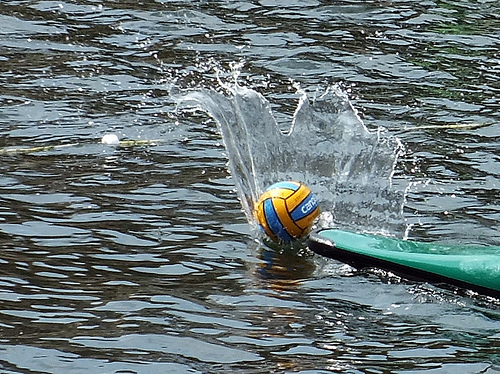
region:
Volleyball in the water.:
[249, 175, 321, 244]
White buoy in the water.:
[97, 132, 120, 147]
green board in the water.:
[305, 221, 497, 297]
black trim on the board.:
[305, 220, 341, 255]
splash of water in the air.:
[165, 57, 427, 237]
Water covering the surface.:
[1, 0, 492, 370]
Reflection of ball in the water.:
[250, 242, 315, 282]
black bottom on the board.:
[308, 223, 498, 304]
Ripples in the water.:
[2, 2, 493, 370]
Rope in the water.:
[1, 119, 497, 161]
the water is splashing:
[149, 32, 430, 250]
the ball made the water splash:
[224, 156, 339, 264]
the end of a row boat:
[291, 212, 498, 300]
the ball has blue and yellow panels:
[210, 141, 340, 256]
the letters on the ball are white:
[285, 178, 327, 228]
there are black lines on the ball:
[242, 164, 342, 250]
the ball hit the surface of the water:
[229, 139, 347, 356]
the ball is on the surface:
[227, 168, 341, 254]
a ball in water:
[228, 146, 317, 250]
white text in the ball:
[294, 177, 324, 222]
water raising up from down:
[183, 60, 447, 195]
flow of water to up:
[174, 48, 404, 178]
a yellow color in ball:
[273, 195, 294, 240]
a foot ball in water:
[228, 145, 313, 255]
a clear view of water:
[29, 18, 496, 178]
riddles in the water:
[24, 193, 374, 370]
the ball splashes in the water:
[175, 78, 476, 270]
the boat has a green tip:
[304, 216, 376, 299]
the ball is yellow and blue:
[245, 145, 434, 312]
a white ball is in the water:
[80, 110, 225, 216]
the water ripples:
[120, 223, 295, 336]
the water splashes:
[80, 13, 477, 220]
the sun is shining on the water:
[3, 23, 294, 268]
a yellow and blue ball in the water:
[258, 176, 320, 243]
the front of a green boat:
[307, 222, 499, 302]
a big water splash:
[165, 68, 418, 244]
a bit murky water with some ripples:
[17, 286, 67, 371]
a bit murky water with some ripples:
[65, 285, 134, 372]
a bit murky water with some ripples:
[125, 287, 202, 364]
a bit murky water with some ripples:
[323, 310, 383, 361]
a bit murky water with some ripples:
[4, 225, 108, 319]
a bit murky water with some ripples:
[76, 212, 185, 322]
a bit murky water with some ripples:
[15, 138, 102, 241]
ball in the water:
[251, 180, 320, 242]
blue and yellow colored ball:
[253, 178, 321, 243]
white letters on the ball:
[299, 192, 318, 217]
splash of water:
[167, 53, 417, 267]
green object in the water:
[309, 218, 499, 291]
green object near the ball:
[303, 214, 497, 297]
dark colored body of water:
[0, 0, 499, 372]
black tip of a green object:
[308, 221, 350, 251]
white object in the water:
[97, 132, 120, 147]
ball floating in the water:
[252, 177, 320, 242]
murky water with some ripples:
[1, 318, 65, 371]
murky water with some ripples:
[115, 310, 187, 365]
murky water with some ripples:
[179, 313, 239, 368]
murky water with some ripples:
[2, 260, 89, 319]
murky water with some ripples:
[96, 239, 170, 311]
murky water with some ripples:
[176, 235, 251, 305]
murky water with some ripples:
[149, 164, 236, 228]